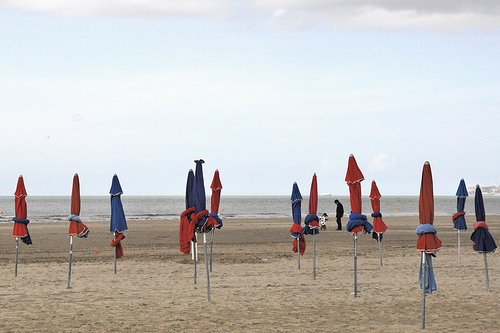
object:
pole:
[482, 254, 489, 292]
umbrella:
[468, 183, 497, 292]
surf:
[0, 194, 500, 224]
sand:
[0, 215, 499, 332]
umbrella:
[11, 173, 33, 277]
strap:
[11, 215, 31, 223]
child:
[318, 211, 329, 232]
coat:
[319, 216, 329, 226]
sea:
[2, 192, 500, 224]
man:
[332, 198, 344, 232]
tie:
[415, 223, 438, 296]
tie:
[209, 211, 223, 228]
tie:
[11, 214, 34, 247]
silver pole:
[67, 232, 73, 289]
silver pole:
[310, 229, 318, 279]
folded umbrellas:
[414, 160, 440, 329]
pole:
[202, 231, 214, 301]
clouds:
[1, 0, 500, 197]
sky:
[0, 0, 499, 197]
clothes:
[335, 202, 344, 218]